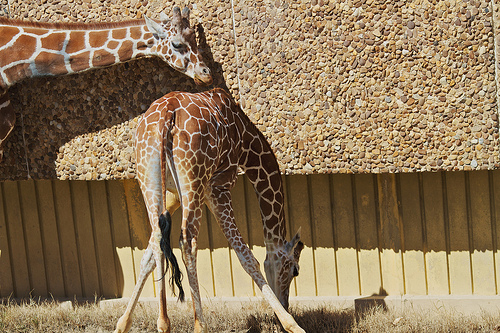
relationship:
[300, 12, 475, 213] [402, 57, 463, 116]
building has rock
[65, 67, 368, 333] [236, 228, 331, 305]
giraffe has head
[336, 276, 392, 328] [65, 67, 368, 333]
shadow of giraffe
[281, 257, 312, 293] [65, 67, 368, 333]
eye of giraffe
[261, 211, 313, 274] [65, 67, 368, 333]
ear of giraffe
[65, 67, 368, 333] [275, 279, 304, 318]
giraffe with nose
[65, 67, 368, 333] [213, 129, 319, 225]
giraffe has neck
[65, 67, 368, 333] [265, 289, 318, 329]
looking for food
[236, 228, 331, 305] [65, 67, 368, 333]
head of giraffe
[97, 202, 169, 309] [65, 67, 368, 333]
leg of giraffe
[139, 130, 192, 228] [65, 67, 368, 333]
tail of giraffe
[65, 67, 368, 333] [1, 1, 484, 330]
giraffe in zoo compound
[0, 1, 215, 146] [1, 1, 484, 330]
giraffe in zoo compound